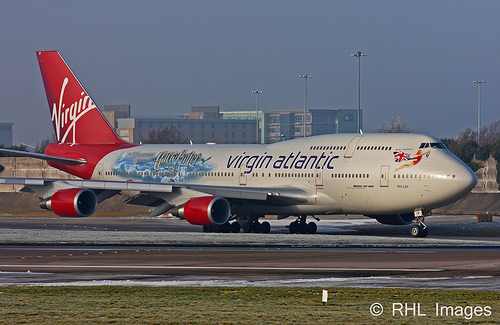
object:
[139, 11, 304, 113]
part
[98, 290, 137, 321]
part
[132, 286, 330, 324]
grass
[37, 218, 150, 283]
part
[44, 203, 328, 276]
runway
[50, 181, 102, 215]
part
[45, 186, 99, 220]
engine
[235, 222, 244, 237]
part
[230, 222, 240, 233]
wheel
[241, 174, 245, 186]
part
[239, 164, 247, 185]
door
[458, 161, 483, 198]
tip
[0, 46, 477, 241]
plane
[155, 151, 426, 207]
side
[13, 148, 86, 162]
edge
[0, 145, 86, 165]
wing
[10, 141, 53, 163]
part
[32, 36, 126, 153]
tail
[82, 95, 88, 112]
letters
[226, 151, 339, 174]
logo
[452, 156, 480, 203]
nose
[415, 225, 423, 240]
front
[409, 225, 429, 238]
wheel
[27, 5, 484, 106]
sky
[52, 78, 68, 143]
letter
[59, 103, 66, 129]
letter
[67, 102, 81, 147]
letter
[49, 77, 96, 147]
logo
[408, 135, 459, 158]
cockpit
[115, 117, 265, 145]
buildings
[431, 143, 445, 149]
windshield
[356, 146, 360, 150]
windows